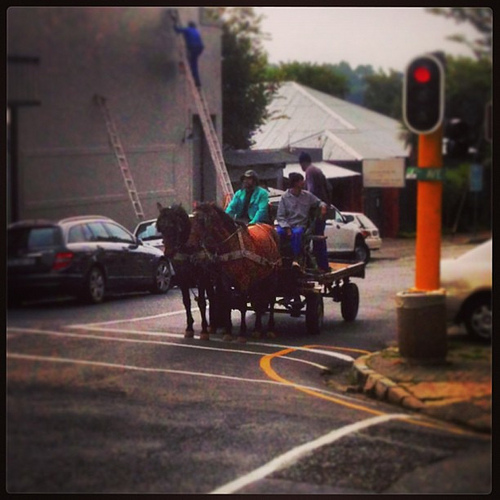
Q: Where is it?
A: This is at the street.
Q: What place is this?
A: It is a street.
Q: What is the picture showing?
A: It is showing a street.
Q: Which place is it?
A: It is a street.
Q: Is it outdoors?
A: Yes, it is outdoors.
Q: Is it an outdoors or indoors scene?
A: It is outdoors.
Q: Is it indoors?
A: No, it is outdoors.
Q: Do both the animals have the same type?
A: Yes, all the animals are horses.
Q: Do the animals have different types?
A: No, all the animals are horses.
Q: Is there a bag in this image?
A: No, there are no bags.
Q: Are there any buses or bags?
A: No, there are no bags or buses.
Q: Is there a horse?
A: Yes, there is a horse.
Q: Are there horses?
A: Yes, there is a horse.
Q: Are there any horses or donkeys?
A: Yes, there is a horse.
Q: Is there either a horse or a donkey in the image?
A: Yes, there is a horse.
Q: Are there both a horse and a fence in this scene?
A: No, there is a horse but no fences.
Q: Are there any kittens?
A: No, there are no kittens.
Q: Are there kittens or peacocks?
A: No, there are no kittens or peacocks.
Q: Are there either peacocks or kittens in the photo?
A: No, there are no kittens or peacocks.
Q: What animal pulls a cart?
A: The horse pulls a cart.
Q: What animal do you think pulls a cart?
A: The animal is a horse.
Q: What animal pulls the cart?
A: The animal is a horse.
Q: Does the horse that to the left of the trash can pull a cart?
A: Yes, the horse pulls a cart.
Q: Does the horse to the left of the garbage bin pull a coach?
A: No, the horse pulls a cart.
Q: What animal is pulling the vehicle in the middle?
A: The horse is pulling the carriage.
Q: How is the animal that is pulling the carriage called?
A: The animal is a horse.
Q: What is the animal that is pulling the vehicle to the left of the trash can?
A: The animal is a horse.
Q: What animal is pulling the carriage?
A: The animal is a horse.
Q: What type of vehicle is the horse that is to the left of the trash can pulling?
A: The horse is pulling the carriage.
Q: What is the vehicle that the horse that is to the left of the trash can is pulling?
A: The vehicle is a carriage.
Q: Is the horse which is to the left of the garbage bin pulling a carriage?
A: Yes, the horse is pulling a carriage.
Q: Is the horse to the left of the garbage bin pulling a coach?
A: No, the horse is pulling a carriage.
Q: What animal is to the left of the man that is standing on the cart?
A: The animal is a horse.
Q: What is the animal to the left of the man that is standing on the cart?
A: The animal is a horse.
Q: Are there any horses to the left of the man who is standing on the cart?
A: Yes, there is a horse to the left of the man.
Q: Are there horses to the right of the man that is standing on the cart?
A: No, the horse is to the left of the man.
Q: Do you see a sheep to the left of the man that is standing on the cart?
A: No, there is a horse to the left of the man.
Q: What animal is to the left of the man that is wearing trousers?
A: The animal is a horse.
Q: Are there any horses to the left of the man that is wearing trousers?
A: Yes, there is a horse to the left of the man.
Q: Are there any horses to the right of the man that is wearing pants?
A: No, the horse is to the left of the man.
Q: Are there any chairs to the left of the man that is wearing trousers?
A: No, there is a horse to the left of the man.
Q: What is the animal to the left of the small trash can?
A: The animal is a horse.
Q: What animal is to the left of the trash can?
A: The animal is a horse.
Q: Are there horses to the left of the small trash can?
A: Yes, there is a horse to the left of the garbage can.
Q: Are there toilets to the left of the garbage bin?
A: No, there is a horse to the left of the garbage bin.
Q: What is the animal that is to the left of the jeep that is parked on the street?
A: The animal is a horse.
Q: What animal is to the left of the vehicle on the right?
A: The animal is a horse.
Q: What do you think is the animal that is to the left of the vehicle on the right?
A: The animal is a horse.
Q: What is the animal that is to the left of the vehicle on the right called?
A: The animal is a horse.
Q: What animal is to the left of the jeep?
A: The animal is a horse.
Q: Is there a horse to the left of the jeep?
A: Yes, there is a horse to the left of the jeep.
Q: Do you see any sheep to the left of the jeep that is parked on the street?
A: No, there is a horse to the left of the jeep.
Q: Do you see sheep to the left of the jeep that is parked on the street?
A: No, there is a horse to the left of the jeep.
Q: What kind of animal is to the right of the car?
A: The animal is a horse.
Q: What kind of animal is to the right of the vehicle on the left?
A: The animal is a horse.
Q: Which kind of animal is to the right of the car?
A: The animal is a horse.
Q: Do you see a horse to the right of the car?
A: Yes, there is a horse to the right of the car.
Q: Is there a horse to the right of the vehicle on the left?
A: Yes, there is a horse to the right of the car.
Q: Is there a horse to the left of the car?
A: No, the horse is to the right of the car.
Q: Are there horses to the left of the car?
A: No, the horse is to the right of the car.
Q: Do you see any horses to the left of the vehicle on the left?
A: No, the horse is to the right of the car.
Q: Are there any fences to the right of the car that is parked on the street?
A: No, there is a horse to the right of the car.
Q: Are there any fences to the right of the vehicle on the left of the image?
A: No, there is a horse to the right of the car.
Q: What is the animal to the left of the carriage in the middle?
A: The animal is a horse.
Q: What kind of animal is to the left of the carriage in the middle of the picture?
A: The animal is a horse.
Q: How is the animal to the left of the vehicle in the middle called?
A: The animal is a horse.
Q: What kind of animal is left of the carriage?
A: The animal is a horse.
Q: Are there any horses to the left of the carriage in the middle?
A: Yes, there is a horse to the left of the carriage.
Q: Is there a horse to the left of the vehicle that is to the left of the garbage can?
A: Yes, there is a horse to the left of the carriage.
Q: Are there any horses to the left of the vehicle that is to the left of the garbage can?
A: Yes, there is a horse to the left of the carriage.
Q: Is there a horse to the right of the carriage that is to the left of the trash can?
A: No, the horse is to the left of the carriage.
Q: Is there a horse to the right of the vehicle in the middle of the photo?
A: No, the horse is to the left of the carriage.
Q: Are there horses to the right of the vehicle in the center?
A: No, the horse is to the left of the carriage.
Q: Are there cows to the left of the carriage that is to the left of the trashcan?
A: No, there is a horse to the left of the carriage.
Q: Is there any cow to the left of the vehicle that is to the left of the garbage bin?
A: No, there is a horse to the left of the carriage.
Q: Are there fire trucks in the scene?
A: No, there are no fire trucks.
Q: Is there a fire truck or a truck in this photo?
A: No, there are no fire trucks or trucks.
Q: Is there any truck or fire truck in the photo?
A: No, there are no fire trucks or trucks.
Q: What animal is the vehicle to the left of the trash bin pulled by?
A: The carriage is pulled by the horse.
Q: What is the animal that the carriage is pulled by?
A: The animal is a horse.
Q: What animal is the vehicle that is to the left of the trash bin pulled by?
A: The carriage is pulled by the horse.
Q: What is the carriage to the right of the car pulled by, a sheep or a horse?
A: The carriage is pulled by a horse.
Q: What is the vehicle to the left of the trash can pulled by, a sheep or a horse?
A: The carriage is pulled by a horse.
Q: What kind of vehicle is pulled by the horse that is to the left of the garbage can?
A: The vehicle is a carriage.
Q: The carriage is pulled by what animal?
A: The carriage is pulled by the horse.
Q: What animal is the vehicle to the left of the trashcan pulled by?
A: The carriage is pulled by the horse.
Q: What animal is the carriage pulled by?
A: The carriage is pulled by the horse.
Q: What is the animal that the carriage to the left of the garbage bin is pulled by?
A: The animal is a horse.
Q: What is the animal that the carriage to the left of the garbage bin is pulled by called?
A: The animal is a horse.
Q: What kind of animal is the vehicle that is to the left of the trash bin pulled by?
A: The carriage is pulled by the horse.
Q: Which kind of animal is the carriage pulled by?
A: The carriage is pulled by the horse.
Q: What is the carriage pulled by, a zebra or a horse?
A: The carriage is pulled by a horse.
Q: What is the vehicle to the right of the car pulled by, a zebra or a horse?
A: The carriage is pulled by a horse.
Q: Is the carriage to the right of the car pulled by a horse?
A: Yes, the carriage is pulled by a horse.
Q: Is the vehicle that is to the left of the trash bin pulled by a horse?
A: Yes, the carriage is pulled by a horse.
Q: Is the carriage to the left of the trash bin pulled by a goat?
A: No, the carriage is pulled by a horse.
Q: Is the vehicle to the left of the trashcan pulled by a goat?
A: No, the carriage is pulled by a horse.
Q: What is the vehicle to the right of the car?
A: The vehicle is a carriage.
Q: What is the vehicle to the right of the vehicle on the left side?
A: The vehicle is a carriage.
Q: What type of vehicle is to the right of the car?
A: The vehicle is a carriage.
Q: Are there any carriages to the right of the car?
A: Yes, there is a carriage to the right of the car.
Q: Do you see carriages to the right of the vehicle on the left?
A: Yes, there is a carriage to the right of the car.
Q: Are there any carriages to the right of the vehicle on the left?
A: Yes, there is a carriage to the right of the car.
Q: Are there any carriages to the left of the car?
A: No, the carriage is to the right of the car.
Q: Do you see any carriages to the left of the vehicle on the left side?
A: No, the carriage is to the right of the car.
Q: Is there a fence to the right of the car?
A: No, there is a carriage to the right of the car.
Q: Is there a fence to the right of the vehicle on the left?
A: No, there is a carriage to the right of the car.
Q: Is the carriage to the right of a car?
A: Yes, the carriage is to the right of a car.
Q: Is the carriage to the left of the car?
A: No, the carriage is to the right of the car.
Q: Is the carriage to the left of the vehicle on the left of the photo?
A: No, the carriage is to the right of the car.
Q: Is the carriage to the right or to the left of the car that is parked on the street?
A: The carriage is to the right of the car.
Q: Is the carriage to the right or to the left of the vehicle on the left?
A: The carriage is to the right of the car.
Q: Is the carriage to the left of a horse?
A: No, the carriage is to the right of a horse.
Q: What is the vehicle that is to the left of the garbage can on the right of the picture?
A: The vehicle is a carriage.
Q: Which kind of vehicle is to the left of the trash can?
A: The vehicle is a carriage.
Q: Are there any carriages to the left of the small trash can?
A: Yes, there is a carriage to the left of the garbage can.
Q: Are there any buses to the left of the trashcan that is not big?
A: No, there is a carriage to the left of the garbage can.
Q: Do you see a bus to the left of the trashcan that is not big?
A: No, there is a carriage to the left of the garbage can.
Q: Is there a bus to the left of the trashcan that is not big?
A: No, there is a carriage to the left of the garbage can.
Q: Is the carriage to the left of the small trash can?
A: Yes, the carriage is to the left of the trash can.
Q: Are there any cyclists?
A: No, there are no cyclists.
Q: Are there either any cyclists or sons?
A: No, there are no cyclists or sons.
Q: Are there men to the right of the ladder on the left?
A: Yes, there is a man to the right of the ladder.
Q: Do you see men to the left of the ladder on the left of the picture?
A: No, the man is to the right of the ladder.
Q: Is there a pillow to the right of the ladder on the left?
A: No, there is a man to the right of the ladder.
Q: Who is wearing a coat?
A: The man is wearing a coat.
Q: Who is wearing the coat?
A: The man is wearing a coat.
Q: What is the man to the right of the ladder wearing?
A: The man is wearing a coat.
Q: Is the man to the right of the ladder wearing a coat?
A: Yes, the man is wearing a coat.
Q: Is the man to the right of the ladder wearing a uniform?
A: No, the man is wearing a coat.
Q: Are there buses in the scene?
A: No, there are no buses.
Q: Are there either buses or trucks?
A: No, there are no buses or trucks.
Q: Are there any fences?
A: No, there are no fences.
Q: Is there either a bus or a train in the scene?
A: No, there are no buses or trains.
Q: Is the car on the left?
A: Yes, the car is on the left of the image.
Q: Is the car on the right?
A: No, the car is on the left of the image.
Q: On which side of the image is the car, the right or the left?
A: The car is on the left of the image.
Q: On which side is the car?
A: The car is on the left of the image.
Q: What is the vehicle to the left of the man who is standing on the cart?
A: The vehicle is a car.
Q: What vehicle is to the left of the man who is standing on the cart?
A: The vehicle is a car.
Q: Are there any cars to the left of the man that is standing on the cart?
A: Yes, there is a car to the left of the man.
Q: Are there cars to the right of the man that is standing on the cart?
A: No, the car is to the left of the man.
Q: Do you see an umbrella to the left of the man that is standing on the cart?
A: No, there is a car to the left of the man.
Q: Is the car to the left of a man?
A: Yes, the car is to the left of a man.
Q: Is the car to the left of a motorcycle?
A: No, the car is to the left of a man.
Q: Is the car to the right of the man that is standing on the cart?
A: No, the car is to the left of the man.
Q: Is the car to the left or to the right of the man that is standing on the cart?
A: The car is to the left of the man.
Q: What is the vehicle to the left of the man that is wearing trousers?
A: The vehicle is a car.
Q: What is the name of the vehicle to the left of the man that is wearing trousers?
A: The vehicle is a car.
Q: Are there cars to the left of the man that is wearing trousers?
A: Yes, there is a car to the left of the man.